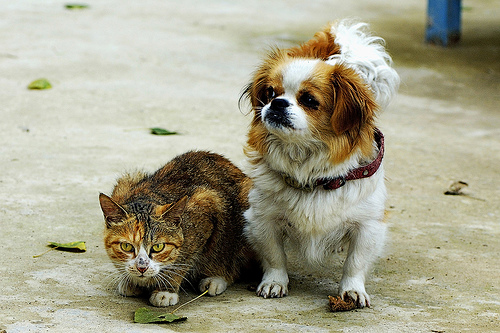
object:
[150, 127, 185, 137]
leaf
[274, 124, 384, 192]
collar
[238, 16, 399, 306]
dog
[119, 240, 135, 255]
eyes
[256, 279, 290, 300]
paw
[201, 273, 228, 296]
paw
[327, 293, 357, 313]
leaf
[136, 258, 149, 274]
nose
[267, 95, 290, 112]
nose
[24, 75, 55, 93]
leaves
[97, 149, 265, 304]
animals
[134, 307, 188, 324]
leaf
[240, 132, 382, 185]
neck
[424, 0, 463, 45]
leg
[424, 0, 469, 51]
table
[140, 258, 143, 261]
dots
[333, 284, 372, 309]
paw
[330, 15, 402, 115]
tail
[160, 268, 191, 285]
whiskers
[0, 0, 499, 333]
concrete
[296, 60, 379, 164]
patches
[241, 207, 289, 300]
leg